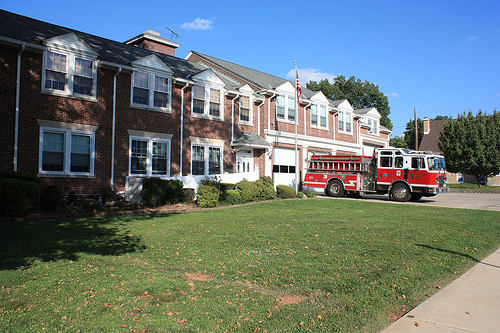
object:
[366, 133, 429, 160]
floor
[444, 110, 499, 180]
leaves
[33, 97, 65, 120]
brick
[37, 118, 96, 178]
window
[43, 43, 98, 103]
window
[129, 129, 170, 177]
window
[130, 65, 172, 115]
window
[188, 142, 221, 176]
window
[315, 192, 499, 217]
driveway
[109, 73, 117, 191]
drain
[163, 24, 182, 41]
antenna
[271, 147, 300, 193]
door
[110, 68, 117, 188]
downpipe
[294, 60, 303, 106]
american flag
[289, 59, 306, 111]
plant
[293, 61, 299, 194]
pole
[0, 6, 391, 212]
building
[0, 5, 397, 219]
fire station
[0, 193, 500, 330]
grass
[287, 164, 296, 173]
window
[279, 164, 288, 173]
window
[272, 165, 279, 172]
window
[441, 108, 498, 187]
tree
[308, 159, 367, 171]
ladder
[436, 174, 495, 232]
driveway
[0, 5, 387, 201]
fire house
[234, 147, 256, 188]
doors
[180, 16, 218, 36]
cloud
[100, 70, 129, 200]
wall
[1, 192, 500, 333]
front lawn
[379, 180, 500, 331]
sidewalk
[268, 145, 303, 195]
garage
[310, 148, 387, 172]
garage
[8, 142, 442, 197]
bottom floor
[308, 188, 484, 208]
drive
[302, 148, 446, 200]
fire truck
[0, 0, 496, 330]
fire department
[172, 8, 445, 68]
sky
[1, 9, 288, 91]
roof